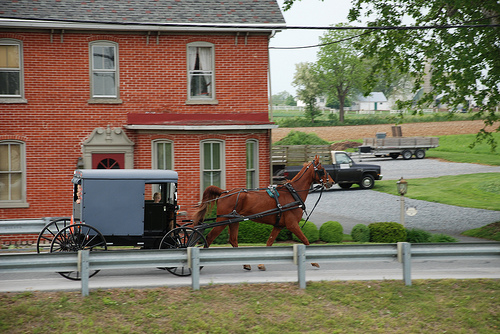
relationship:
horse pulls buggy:
[193, 154, 336, 269] [38, 169, 208, 281]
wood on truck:
[272, 144, 333, 166] [276, 145, 383, 190]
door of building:
[92, 151, 126, 168] [0, 1, 288, 248]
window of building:
[185, 39, 218, 106] [0, 1, 288, 248]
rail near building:
[2, 242, 499, 297] [0, 1, 288, 248]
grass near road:
[375, 173, 500, 214] [2, 242, 499, 297]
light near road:
[396, 177, 409, 229] [1, 252, 496, 292]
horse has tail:
[193, 154, 336, 269] [190, 187, 223, 227]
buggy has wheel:
[38, 169, 208, 281] [160, 225, 210, 277]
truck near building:
[276, 145, 383, 190] [0, 1, 288, 248]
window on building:
[185, 39, 218, 106] [0, 1, 288, 248]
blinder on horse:
[318, 169, 324, 177] [193, 154, 336, 269]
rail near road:
[2, 242, 499, 297] [1, 252, 496, 292]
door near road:
[92, 151, 126, 168] [1, 252, 496, 292]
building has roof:
[0, 1, 288, 248] [0, 1, 286, 26]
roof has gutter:
[0, 1, 286, 26] [0, 18, 287, 33]